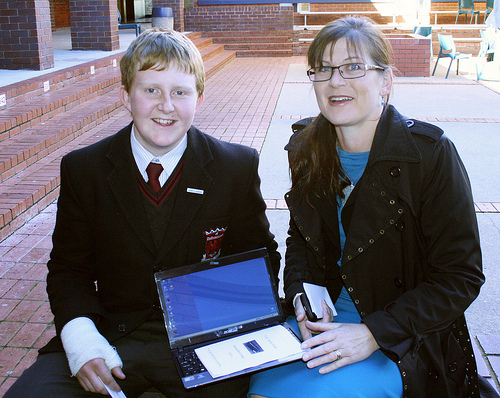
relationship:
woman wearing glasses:
[247, 16, 485, 398] [306, 62, 385, 84]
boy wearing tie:
[4, 27, 282, 397] [145, 163, 164, 194]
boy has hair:
[4, 27, 282, 397] [119, 28, 205, 97]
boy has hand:
[4, 27, 282, 397] [59, 317, 126, 397]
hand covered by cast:
[59, 317, 126, 397] [60, 314, 126, 376]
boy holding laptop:
[4, 27, 282, 397] [154, 245, 310, 392]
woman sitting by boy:
[247, 16, 485, 398] [4, 27, 282, 397]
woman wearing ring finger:
[247, 16, 485, 398] [334, 349, 343, 360]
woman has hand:
[247, 16, 485, 398] [302, 320, 381, 375]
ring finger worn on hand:
[334, 349, 343, 360] [302, 320, 381, 375]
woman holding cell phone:
[247, 16, 485, 398] [300, 292, 319, 323]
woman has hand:
[247, 16, 485, 398] [293, 294, 335, 342]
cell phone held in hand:
[300, 292, 319, 323] [293, 294, 335, 342]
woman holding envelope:
[247, 16, 485, 398] [303, 281, 340, 319]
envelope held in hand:
[303, 281, 340, 319] [293, 294, 335, 342]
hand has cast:
[59, 317, 126, 397] [60, 314, 126, 376]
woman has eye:
[247, 16, 485, 398] [318, 65, 331, 74]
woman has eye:
[247, 16, 485, 398] [346, 64, 359, 71]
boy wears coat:
[4, 27, 282, 397] [39, 119, 282, 353]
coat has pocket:
[39, 119, 282, 353] [186, 214, 234, 266]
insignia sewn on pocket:
[201, 224, 230, 264] [186, 214, 234, 266]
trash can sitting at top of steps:
[150, 7, 174, 28] [1, 31, 237, 243]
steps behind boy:
[1, 31, 237, 243] [4, 27, 282, 397]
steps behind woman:
[1, 31, 237, 243] [247, 16, 485, 398]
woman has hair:
[247, 16, 485, 398] [288, 13, 403, 211]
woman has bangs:
[247, 16, 485, 398] [306, 29, 369, 68]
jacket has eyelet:
[283, 103, 485, 396] [389, 198, 396, 205]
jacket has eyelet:
[283, 103, 485, 396] [379, 227, 387, 236]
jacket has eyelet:
[283, 103, 485, 396] [345, 253, 354, 262]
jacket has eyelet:
[283, 103, 485, 396] [347, 287, 351, 292]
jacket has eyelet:
[283, 103, 485, 396] [400, 370, 408, 378]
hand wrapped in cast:
[59, 317, 126, 397] [60, 314, 126, 376]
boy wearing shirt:
[4, 27, 282, 397] [130, 122, 189, 188]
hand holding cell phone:
[293, 294, 335, 342] [300, 292, 319, 323]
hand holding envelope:
[293, 294, 335, 342] [303, 281, 340, 319]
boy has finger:
[4, 27, 282, 397] [90, 357, 122, 393]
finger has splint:
[90, 357, 122, 393] [97, 373, 129, 398]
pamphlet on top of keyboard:
[195, 324, 304, 379] [169, 322, 312, 391]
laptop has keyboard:
[154, 245, 310, 392] [169, 322, 312, 391]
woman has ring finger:
[247, 16, 485, 398] [306, 349, 345, 369]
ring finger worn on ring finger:
[334, 349, 343, 360] [306, 349, 345, 369]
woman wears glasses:
[247, 16, 485, 398] [306, 62, 385, 84]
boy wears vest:
[4, 27, 282, 397] [130, 146, 190, 207]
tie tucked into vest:
[145, 163, 164, 194] [130, 146, 190, 207]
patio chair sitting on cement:
[431, 33, 474, 76] [282, 56, 477, 84]